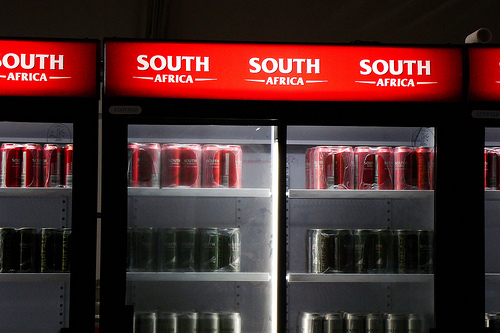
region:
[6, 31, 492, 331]
three fridges full of drinks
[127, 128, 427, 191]
top row of middle fridge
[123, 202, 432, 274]
second shelf of middle fridge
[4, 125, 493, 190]
red cans of drink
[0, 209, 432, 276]
green cans of drinks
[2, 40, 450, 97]
white lettering on red background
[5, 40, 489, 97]
red tops of fridges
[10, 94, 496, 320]
black frames of fridges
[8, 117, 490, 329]
glass of fridge cases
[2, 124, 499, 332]
aluminum cans in fridges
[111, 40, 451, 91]
red and white sign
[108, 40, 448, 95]
red and white sign with text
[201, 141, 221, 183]
red and silver can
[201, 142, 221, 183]
red and silver soda can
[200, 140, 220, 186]
red and silver bevarage can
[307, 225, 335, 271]
black and silver can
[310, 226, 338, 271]
black and silver soda can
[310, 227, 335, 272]
black and silver beverage can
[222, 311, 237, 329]
silver and white can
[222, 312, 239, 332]
silver and white metal beverage can in a cooler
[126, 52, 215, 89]
white lettering on a red sign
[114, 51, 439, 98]
backlit red sign of the cooler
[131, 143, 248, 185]
red soda cans wrapped in plastic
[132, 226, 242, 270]
green soda cans wrapped in plastic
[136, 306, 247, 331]
gold soda cans wrapped in plastic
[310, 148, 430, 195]
red soda cans on the top shelf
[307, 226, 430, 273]
black soda cans on the middle shelf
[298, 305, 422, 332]
gold soda cans on the bottom shelf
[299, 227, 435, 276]
black soda cans wrapped in plastic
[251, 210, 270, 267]
white rear surface of the cooler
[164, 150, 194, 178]
Reddish cans of drink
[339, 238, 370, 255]
Blackish cans of drink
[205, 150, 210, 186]
Wrapper around a can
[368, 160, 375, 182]
Space left by a wrapper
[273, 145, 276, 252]
A tube of light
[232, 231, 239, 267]
Light reflecting from a wrapper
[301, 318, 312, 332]
Light reflecting from a can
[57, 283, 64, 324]
Holes in a fridge wall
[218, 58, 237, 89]
A red surface above the cans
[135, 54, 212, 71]
White words on a red surface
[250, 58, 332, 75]
word south in white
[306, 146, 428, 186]
red cans of soda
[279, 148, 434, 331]
three shelves displayed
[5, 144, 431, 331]
assorted drinks of soda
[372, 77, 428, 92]
word africa is under south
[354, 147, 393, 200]
soda has opened cellophane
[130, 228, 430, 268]
green cans of soda on shelf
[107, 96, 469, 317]
display case has door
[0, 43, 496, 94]
red background on sign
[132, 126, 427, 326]
light is on in display